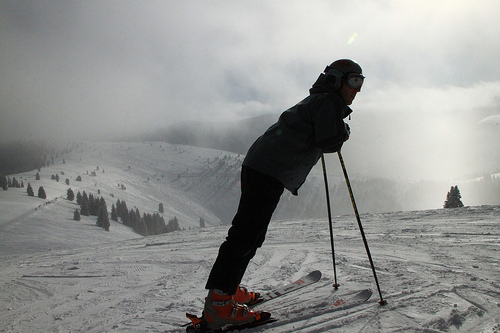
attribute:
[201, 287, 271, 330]
boots — orange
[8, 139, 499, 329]
snow — white, clear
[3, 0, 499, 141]
sky — cloudy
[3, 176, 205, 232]
trees — pine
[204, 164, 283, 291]
pants — black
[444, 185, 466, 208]
tree — standing